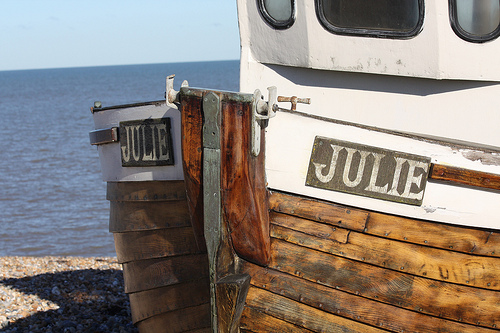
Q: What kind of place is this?
A: It is a lake.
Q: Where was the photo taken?
A: It was taken at the lake.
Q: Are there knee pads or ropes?
A: No, there are no ropes or knee pads.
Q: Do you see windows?
A: Yes, there are windows.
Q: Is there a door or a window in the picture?
A: Yes, there are windows.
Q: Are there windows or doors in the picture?
A: Yes, there are windows.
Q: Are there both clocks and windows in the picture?
A: No, there are windows but no clocks.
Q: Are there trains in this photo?
A: No, there are no trains.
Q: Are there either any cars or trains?
A: No, there are no trains or cars.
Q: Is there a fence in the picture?
A: No, there are no fences.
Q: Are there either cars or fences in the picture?
A: No, there are no fences or cars.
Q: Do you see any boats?
A: Yes, there is a boat.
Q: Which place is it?
A: It is a lake.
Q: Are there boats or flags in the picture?
A: Yes, there is a boat.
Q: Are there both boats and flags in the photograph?
A: No, there is a boat but no flags.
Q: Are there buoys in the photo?
A: No, there are no buoys.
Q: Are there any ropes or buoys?
A: No, there are no buoys or ropes.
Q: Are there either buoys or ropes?
A: No, there are no buoys or ropes.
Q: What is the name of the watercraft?
A: The watercraft is a boat.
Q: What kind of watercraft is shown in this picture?
A: The watercraft is a boat.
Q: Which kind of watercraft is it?
A: The watercraft is a boat.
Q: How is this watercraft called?
A: That is a boat.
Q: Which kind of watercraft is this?
A: That is a boat.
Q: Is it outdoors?
A: Yes, it is outdoors.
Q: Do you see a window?
A: Yes, there are windows.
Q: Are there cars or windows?
A: Yes, there are windows.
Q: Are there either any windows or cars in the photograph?
A: Yes, there are windows.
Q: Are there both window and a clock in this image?
A: No, there are windows but no clocks.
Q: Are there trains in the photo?
A: No, there are no trains.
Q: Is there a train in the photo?
A: No, there are no trains.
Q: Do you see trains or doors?
A: No, there are no trains or doors.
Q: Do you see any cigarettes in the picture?
A: No, there are no cigarettes.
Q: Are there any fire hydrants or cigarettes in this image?
A: No, there are no cigarettes or fire hydrants.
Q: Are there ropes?
A: No, there are no ropes.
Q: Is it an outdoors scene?
A: Yes, it is outdoors.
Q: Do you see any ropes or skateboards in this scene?
A: No, there are no ropes or skateboards.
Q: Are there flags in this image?
A: No, there are no flags.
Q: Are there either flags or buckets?
A: No, there are no flags or buckets.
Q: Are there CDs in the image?
A: No, there are no cds.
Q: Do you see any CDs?
A: No, there are no cds.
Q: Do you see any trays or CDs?
A: No, there are no CDs or trays.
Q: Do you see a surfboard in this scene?
A: No, there are no surfboards.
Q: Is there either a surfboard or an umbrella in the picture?
A: No, there are no surfboards or umbrellas.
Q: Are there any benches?
A: No, there are no benches.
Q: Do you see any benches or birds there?
A: No, there are no benches or birds.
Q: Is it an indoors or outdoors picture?
A: It is outdoors.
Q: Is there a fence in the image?
A: No, there are no fences.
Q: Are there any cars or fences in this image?
A: No, there are no fences or cars.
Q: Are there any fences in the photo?
A: No, there are no fences.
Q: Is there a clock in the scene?
A: No, there are no clocks.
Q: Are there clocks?
A: No, there are no clocks.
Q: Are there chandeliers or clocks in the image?
A: No, there are no clocks or chandeliers.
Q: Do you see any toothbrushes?
A: No, there are no toothbrushes.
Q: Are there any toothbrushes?
A: No, there are no toothbrushes.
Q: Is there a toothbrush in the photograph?
A: No, there are no toothbrushes.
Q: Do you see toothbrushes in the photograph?
A: No, there are no toothbrushes.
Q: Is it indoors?
A: No, it is outdoors.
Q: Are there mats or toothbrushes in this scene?
A: No, there are no toothbrushes or mats.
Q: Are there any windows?
A: Yes, there are windows.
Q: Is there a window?
A: Yes, there are windows.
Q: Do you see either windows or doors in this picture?
A: Yes, there are windows.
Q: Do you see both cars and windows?
A: No, there are windows but no cars.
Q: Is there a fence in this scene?
A: No, there are no fences.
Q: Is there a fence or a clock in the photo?
A: No, there are no fences or clocks.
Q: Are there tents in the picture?
A: No, there are no tents.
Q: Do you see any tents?
A: No, there are no tents.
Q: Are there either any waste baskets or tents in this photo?
A: No, there are no tents or waste baskets.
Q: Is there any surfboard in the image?
A: No, there are no surfboards.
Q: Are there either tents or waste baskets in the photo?
A: No, there are no tents or waste baskets.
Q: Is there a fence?
A: No, there are no fences.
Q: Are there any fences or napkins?
A: No, there are no fences or napkins.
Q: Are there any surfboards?
A: No, there are no surfboards.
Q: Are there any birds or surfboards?
A: No, there are no surfboards or birds.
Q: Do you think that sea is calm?
A: Yes, the sea is calm.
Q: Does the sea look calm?
A: Yes, the sea is calm.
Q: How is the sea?
A: The sea is calm.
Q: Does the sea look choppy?
A: No, the sea is calm.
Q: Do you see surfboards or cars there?
A: No, there are no surfboards or cars.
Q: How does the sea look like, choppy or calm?
A: The sea is calm.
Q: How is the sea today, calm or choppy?
A: The sea is calm.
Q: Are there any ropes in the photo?
A: No, there are no ropes.